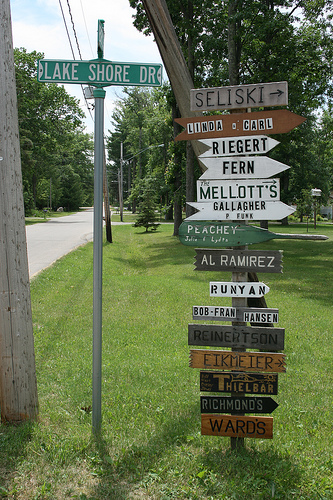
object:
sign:
[190, 81, 288, 112]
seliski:
[195, 86, 264, 107]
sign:
[174, 109, 308, 141]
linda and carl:
[187, 118, 273, 135]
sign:
[197, 135, 281, 157]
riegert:
[213, 138, 268, 155]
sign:
[199, 156, 292, 179]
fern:
[223, 161, 255, 174]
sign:
[196, 180, 280, 202]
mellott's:
[200, 185, 277, 199]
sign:
[183, 200, 297, 220]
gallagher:
[213, 201, 265, 211]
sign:
[193, 249, 284, 274]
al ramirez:
[201, 254, 276, 267]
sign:
[188, 323, 285, 351]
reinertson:
[194, 330, 277, 345]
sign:
[189, 349, 287, 372]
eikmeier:
[203, 354, 273, 369]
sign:
[200, 370, 278, 395]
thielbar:
[213, 375, 274, 394]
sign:
[37, 58, 163, 87]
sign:
[178, 219, 329, 247]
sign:
[200, 396, 279, 412]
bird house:
[310, 187, 322, 196]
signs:
[192, 305, 279, 324]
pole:
[230, 108, 250, 451]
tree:
[13, 47, 77, 218]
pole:
[91, 88, 104, 433]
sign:
[209, 281, 270, 298]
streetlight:
[120, 143, 164, 222]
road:
[24, 203, 112, 280]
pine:
[132, 181, 162, 233]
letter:
[45, 62, 52, 79]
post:
[314, 196, 316, 229]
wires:
[56, 0, 113, 139]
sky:
[10, 2, 333, 165]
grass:
[2, 211, 333, 499]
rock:
[56, 207, 63, 212]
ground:
[23, 217, 83, 279]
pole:
[0, 0, 41, 421]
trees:
[106, 0, 333, 235]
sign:
[201, 414, 274, 439]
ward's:
[209, 418, 266, 435]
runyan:
[211, 284, 266, 294]